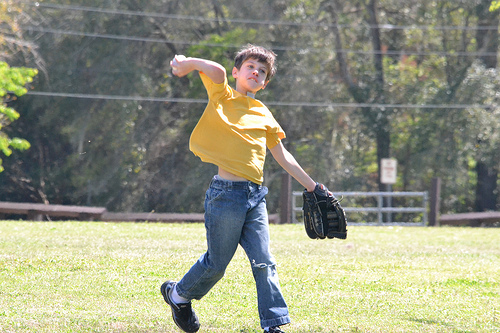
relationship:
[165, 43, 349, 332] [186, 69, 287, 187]
boy wearing short sleeves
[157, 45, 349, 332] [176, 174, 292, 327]
boy wearing blue jeans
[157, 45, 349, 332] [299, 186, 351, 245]
boy has a baseball mitt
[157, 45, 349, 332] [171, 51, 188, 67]
boy holding baseball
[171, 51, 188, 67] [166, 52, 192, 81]
baseball in boys hand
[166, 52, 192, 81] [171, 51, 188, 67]
hand holding baseball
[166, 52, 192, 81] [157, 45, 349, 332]
hand of boy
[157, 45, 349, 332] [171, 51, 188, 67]
boy throwing baseball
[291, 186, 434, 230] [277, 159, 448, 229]
gate with wood posts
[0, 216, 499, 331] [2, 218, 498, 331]
field of grass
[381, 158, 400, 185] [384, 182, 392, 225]
sign on pole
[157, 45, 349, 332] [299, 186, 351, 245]
boy with baseball mitt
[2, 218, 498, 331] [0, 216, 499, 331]
grass on field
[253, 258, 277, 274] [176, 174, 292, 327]
tear on blue jeans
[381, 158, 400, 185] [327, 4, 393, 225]
sign by tree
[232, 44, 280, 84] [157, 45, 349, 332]
hair of boy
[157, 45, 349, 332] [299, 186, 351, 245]
boy wearing baseball mitt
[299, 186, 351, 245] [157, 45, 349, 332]
baseball mitt on boy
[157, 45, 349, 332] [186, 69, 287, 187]
boy wearing a short sleeves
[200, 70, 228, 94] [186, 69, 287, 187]
sleeve of short sleeves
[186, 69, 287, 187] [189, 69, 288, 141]
short sleeves has short sleeves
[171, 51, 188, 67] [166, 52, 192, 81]
baseball in hand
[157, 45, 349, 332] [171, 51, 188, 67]
boy pitching baseball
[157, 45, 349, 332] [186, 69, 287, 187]
boy wearing short sleeves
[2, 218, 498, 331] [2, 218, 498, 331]
grass on grass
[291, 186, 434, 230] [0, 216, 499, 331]
gate by field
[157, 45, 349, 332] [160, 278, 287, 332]
boy wearing sneakers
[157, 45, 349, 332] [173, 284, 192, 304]
boy wearing socks